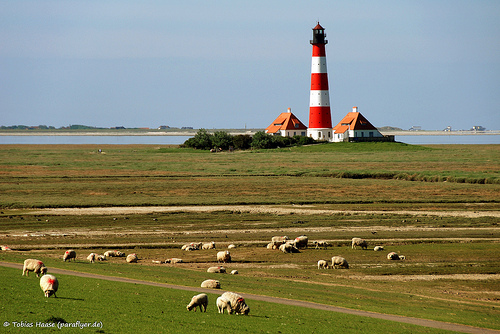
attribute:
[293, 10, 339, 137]
lighthouse — red, white